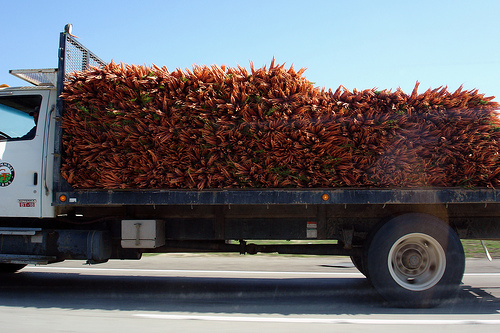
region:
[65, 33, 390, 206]
a truck that is full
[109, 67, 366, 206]
a truck with a pile of plants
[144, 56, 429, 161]
plants that are piled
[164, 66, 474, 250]
plants that are stacked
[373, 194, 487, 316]
truck with a tire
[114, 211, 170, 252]
a truck with a box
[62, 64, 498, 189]
Plants on the back of a truck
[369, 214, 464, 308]
A back tire on a truck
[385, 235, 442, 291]
A rim on a truck tire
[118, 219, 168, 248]
A white box under a truck trailer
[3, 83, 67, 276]
The white cab of a truck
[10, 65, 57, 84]
A wire ledge over a truck roof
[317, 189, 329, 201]
A round orange light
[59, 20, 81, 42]
A bird perched on a truck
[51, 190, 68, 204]
An orange light on the side of a truck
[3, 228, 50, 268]
A step on the driver's side of a truck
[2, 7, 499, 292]
white truck transporting corn in the husk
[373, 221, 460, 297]
black rear tire on truck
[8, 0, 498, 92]
clear blue cloudless sky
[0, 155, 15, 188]
green and black logo on truck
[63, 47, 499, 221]
flatbed full of corn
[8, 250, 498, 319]
shadow of truck on ground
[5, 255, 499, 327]
grey concrete road with truck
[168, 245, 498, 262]
green grassy ground next to road behind truck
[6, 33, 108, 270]
white cab of truck with metal shield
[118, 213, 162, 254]
white box under flatbed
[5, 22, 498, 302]
this is a truck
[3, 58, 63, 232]
white front of truck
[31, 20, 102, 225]
metal back on truck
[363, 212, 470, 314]
back tire on truck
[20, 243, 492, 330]
shadow of the truck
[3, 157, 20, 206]
decal on the truck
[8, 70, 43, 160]
person in the truck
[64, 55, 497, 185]
cargo on the bed of a truck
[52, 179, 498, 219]
flatbed trailer on a truck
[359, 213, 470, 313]
rear tire on a truck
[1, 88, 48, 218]
white door on a truck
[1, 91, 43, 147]
driver's side window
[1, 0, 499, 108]
light blue colored sky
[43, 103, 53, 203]
silver handle on the truck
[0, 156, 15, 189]
logo on the truck door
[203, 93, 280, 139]
large section of brown products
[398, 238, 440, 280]
silver bolts in wheel